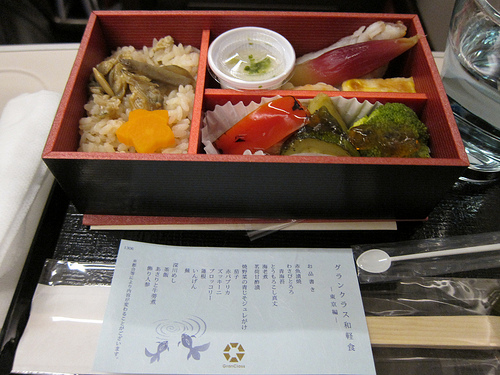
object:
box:
[41, 10, 471, 220]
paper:
[91, 239, 377, 373]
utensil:
[356, 242, 499, 274]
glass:
[441, 0, 500, 186]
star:
[116, 108, 177, 154]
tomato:
[212, 96, 311, 155]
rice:
[78, 36, 198, 153]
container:
[207, 26, 297, 89]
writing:
[333, 263, 356, 352]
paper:
[200, 95, 383, 157]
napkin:
[1, 88, 64, 257]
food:
[117, 110, 174, 154]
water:
[441, 40, 500, 192]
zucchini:
[281, 128, 360, 159]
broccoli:
[348, 101, 432, 158]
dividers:
[188, 29, 211, 154]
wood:
[364, 313, 499, 350]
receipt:
[93, 238, 376, 374]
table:
[0, 101, 500, 375]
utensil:
[365, 315, 499, 349]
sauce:
[219, 43, 284, 79]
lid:
[207, 26, 296, 89]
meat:
[89, 53, 197, 110]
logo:
[223, 342, 245, 361]